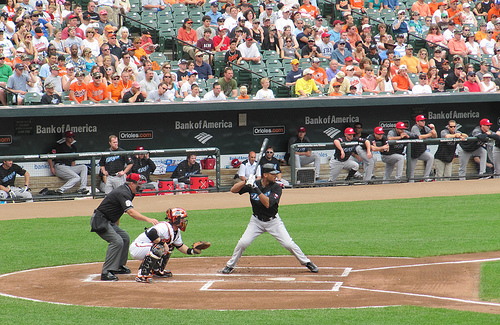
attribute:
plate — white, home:
[270, 275, 297, 281]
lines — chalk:
[133, 241, 355, 318]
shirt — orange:
[71, 80, 86, 100]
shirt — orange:
[89, 80, 106, 99]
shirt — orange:
[108, 81, 123, 97]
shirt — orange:
[120, 80, 133, 95]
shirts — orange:
[70, 79, 137, 103]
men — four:
[71, 61, 140, 103]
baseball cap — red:
[340, 125, 355, 135]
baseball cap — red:
[373, 122, 383, 135]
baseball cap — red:
[393, 120, 406, 130]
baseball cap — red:
[413, 111, 426, 122]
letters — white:
[165, 114, 244, 142]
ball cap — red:
[342, 124, 354, 140]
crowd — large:
[0, 0, 499, 105]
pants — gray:
[223, 215, 310, 275]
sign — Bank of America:
[134, 81, 294, 160]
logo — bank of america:
[56, 99, 327, 167]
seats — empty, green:
[119, 3, 206, 38]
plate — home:
[256, 269, 298, 287]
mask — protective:
[166, 207, 188, 232]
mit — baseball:
[189, 238, 211, 265]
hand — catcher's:
[187, 231, 210, 260]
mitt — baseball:
[191, 237, 211, 256]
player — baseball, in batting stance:
[230, 158, 325, 285]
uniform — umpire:
[87, 184, 141, 272]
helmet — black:
[258, 164, 283, 179]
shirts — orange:
[63, 78, 145, 100]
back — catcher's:
[134, 220, 168, 238]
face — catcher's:
[178, 215, 188, 229]